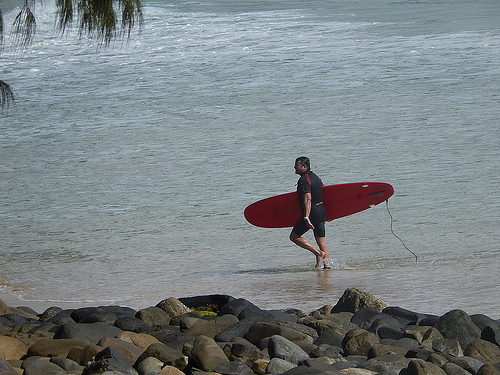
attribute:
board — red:
[241, 183, 395, 228]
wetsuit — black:
[289, 170, 328, 237]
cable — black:
[382, 198, 421, 260]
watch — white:
[302, 217, 308, 222]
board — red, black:
[240, 180, 391, 229]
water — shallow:
[2, 226, 493, 316]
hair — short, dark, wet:
[292, 154, 312, 167]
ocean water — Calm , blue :
[35, 91, 202, 223]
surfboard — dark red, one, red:
[246, 180, 393, 227]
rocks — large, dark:
[2, 293, 494, 371]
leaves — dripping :
[0, 0, 147, 56]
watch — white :
[304, 215, 307, 218]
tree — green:
[0, 0, 143, 112]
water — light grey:
[0, 0, 498, 319]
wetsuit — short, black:
[291, 168, 326, 238]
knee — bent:
[288, 225, 305, 245]